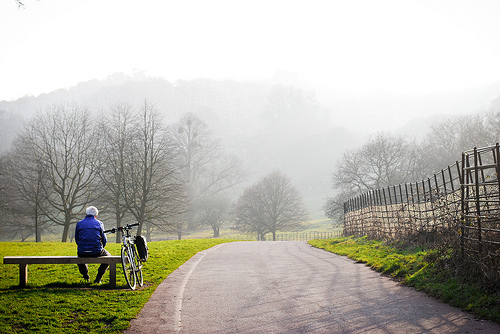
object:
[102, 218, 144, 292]
bike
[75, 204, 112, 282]
man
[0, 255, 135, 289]
bench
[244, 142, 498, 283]
fence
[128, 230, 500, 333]
road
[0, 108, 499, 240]
trees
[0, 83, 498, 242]
mountains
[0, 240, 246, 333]
grass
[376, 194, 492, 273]
vines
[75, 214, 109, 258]
coat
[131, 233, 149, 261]
bag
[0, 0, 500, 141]
sky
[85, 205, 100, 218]
hair